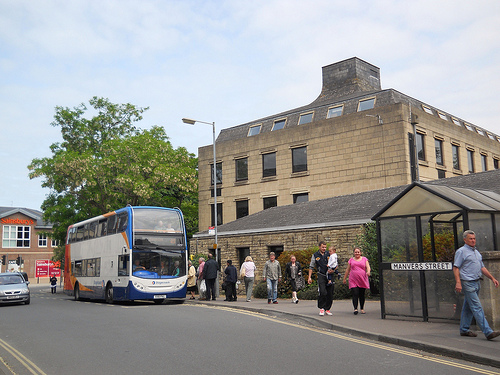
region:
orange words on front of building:
[3, 212, 42, 227]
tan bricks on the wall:
[319, 144, 375, 174]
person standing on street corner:
[44, 270, 59, 294]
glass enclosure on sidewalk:
[356, 177, 478, 312]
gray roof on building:
[216, 189, 369, 243]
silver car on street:
[4, 260, 46, 304]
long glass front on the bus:
[121, 201, 199, 300]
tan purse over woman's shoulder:
[233, 255, 259, 287]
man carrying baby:
[303, 236, 348, 303]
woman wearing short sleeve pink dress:
[338, 238, 383, 294]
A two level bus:
[64, 210, 186, 294]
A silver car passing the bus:
[0, 276, 30, 301]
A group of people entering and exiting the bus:
[198, 255, 480, 314]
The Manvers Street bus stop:
[388, 178, 470, 338]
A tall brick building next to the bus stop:
[219, 85, 471, 204]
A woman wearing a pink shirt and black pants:
[343, 241, 373, 300]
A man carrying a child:
[316, 240, 343, 302]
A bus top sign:
[388, 258, 455, 273]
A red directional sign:
[39, 254, 56, 278]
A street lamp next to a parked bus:
[185, 108, 232, 291]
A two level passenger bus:
[60, 201, 196, 306]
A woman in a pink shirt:
[340, 243, 377, 315]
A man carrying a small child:
[307, 237, 339, 316]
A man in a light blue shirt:
[447, 223, 499, 350]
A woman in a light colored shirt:
[236, 253, 261, 299]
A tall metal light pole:
[177, 116, 227, 289]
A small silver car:
[0, 270, 34, 311]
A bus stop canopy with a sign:
[365, 180, 498, 335]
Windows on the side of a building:
[232, 138, 319, 192]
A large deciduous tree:
[25, 95, 200, 240]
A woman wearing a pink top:
[345, 245, 369, 315]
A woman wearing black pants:
[345, 247, 372, 314]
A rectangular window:
[288, 141, 310, 176]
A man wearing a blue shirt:
[453, 230, 495, 338]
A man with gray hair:
[460, 228, 478, 248]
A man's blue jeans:
[458, 281, 492, 333]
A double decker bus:
[62, 210, 189, 302]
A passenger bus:
[66, 205, 190, 305]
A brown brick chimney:
[318, 56, 383, 91]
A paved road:
[3, 314, 360, 371]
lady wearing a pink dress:
[343, 243, 378, 314]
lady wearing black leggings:
[343, 245, 371, 307]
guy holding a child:
[308, 240, 343, 318]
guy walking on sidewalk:
[446, 223, 499, 349]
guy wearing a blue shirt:
[446, 226, 499, 346]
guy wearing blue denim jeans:
[446, 225, 498, 347]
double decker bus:
[56, 200, 191, 310]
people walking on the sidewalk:
[193, 240, 378, 316]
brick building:
[183, 65, 475, 223]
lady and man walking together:
[260, 247, 305, 308]